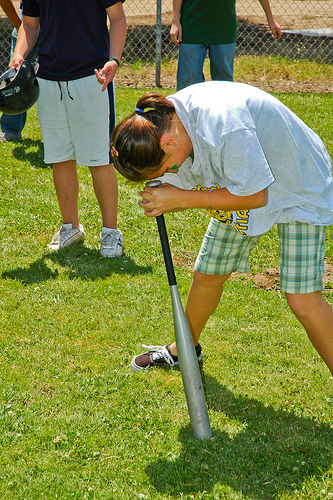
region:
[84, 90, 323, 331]
a woman with her head on bat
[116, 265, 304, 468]
a bat standing up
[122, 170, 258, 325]
a woman holding a bat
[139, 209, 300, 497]
a silver bat on the ground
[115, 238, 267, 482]
a silver baseball bat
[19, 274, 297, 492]
a field of grass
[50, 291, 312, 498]
a field of green grass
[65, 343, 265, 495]
a grass field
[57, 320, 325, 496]
a green grass field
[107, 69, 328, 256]
a woman with her hair up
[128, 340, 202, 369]
brown shoe with white laces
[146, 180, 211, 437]
silver baseball bat with black handle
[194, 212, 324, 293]
green, blue, and white plaid shorts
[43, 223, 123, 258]
old white tennis shoes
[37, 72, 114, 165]
white shorts with navy side stripe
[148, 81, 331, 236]
gray tee shirt with yellow and black writing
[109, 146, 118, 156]
two orange hair barettes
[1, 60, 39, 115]
shiny black batting helmet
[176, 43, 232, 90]
loose fitting denim blue jeans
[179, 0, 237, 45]
hunter green tee shirt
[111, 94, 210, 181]
Woman with her hair in a ponytail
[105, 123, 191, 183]
Woman with a barrette in her hair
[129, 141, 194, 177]
Woman with green paint on her face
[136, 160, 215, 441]
Woman leaning on a grey baseball bat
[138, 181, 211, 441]
Woman holding an aluminum baseball bat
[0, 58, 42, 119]
Man holding baseball helmet in hand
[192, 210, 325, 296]
Woman wearing plaid short pants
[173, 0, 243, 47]
Man wearing a green shirt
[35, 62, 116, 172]
Man wearing white and blue shorts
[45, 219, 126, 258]
Man wearing white tennis shoes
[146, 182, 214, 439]
grey metal baseball bat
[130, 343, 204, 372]
brown and white sneaker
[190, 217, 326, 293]
green plaid cotton shorts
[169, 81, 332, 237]
white cotton tee shirt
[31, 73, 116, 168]
white and blue shorts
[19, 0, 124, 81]
blue cotton tee shirt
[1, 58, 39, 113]
black plastic batting helmet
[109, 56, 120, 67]
black band on wrist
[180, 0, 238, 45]
green cotton tee shirt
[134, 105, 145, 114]
blue band in hair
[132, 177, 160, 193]
silver handle form bat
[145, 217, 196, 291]
black rubber on end of bat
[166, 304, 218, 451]
metal front of bat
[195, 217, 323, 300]
plaid shorts on legs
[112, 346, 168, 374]
brown shoes on feet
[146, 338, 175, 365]
white laces on shoes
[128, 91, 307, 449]
girl holding baseball bat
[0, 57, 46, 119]
black batters helmet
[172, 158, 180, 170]
green paint on woman's face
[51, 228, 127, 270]
white shoes on man's feet